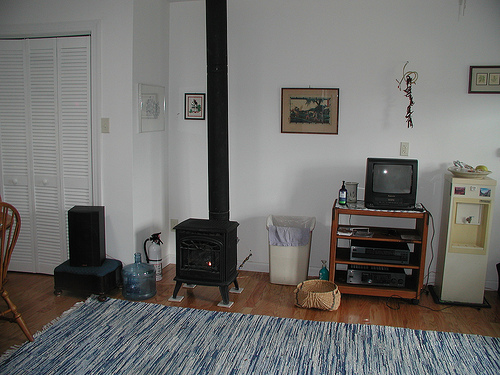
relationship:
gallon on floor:
[117, 248, 161, 303] [4, 268, 497, 372]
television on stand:
[361, 152, 426, 220] [327, 202, 433, 308]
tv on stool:
[359, 151, 424, 211] [323, 193, 434, 303]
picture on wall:
[269, 83, 346, 138] [166, 10, 492, 288]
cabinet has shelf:
[331, 197, 431, 304] [335, 197, 425, 217]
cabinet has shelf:
[331, 197, 431, 304] [336, 223, 421, 243]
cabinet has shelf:
[331, 197, 431, 304] [335, 247, 420, 269]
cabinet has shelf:
[331, 197, 431, 304] [332, 270, 417, 292]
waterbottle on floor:
[121, 247, 158, 297] [2, 264, 483, 363]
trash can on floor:
[271, 212, 319, 289] [2, 264, 483, 363]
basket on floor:
[290, 279, 341, 312] [4, 268, 497, 372]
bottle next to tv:
[335, 180, 351, 207] [363, 157, 422, 210]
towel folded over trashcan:
[265, 223, 313, 245] [266, 211, 316, 287]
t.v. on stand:
[363, 155, 418, 210] [329, 193, 428, 301]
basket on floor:
[280, 248, 356, 315] [349, 293, 442, 330]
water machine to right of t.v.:
[436, 156, 494, 313] [360, 146, 420, 214]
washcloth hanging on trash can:
[267, 223, 312, 249] [264, 212, 315, 285]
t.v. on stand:
[363, 155, 418, 210] [328, 192, 433, 307]